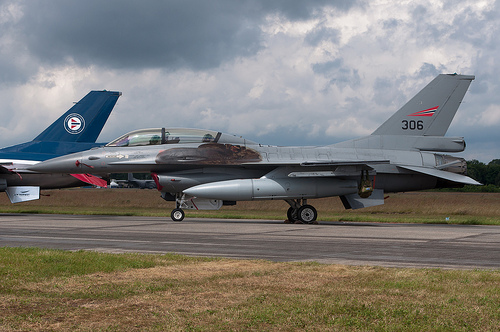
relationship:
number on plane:
[400, 120, 428, 134] [28, 71, 485, 223]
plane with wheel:
[28, 71, 485, 223] [170, 202, 185, 223]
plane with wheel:
[28, 71, 485, 223] [288, 204, 317, 224]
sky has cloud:
[1, 3, 499, 168] [226, 52, 352, 124]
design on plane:
[408, 105, 439, 120] [28, 71, 485, 223]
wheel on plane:
[170, 202, 185, 223] [28, 71, 485, 223]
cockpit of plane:
[116, 123, 224, 145] [28, 71, 485, 223]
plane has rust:
[28, 71, 485, 223] [163, 141, 262, 166]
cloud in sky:
[226, 52, 352, 124] [1, 3, 499, 168]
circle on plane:
[63, 113, 86, 133] [28, 71, 485, 223]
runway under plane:
[1, 210, 499, 274] [28, 71, 485, 223]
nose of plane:
[25, 153, 84, 173] [28, 71, 485, 223]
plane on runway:
[28, 71, 485, 223] [1, 210, 499, 274]